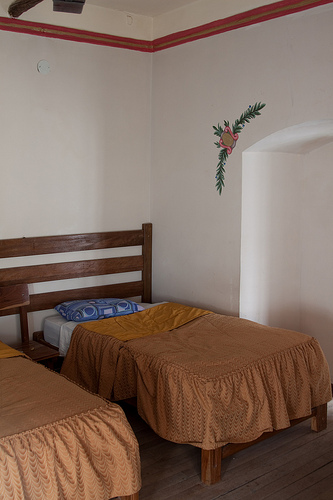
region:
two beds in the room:
[0, 295, 325, 498]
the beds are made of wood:
[1, 224, 330, 498]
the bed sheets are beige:
[1, 303, 327, 498]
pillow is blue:
[58, 292, 141, 322]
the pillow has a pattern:
[59, 289, 137, 322]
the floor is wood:
[132, 393, 332, 495]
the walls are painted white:
[0, 1, 331, 373]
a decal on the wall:
[212, 101, 264, 194]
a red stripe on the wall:
[0, 1, 328, 50]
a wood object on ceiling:
[7, 0, 81, 21]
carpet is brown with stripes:
[244, 455, 287, 493]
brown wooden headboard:
[49, 229, 166, 295]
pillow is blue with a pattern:
[53, 294, 146, 333]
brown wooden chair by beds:
[0, 275, 60, 369]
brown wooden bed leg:
[202, 441, 233, 498]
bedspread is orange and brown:
[158, 348, 236, 417]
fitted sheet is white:
[39, 311, 85, 368]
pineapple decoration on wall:
[200, 79, 263, 194]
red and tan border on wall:
[156, 9, 284, 61]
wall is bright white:
[190, 217, 238, 275]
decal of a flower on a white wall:
[207, 100, 270, 196]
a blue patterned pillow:
[53, 292, 145, 318]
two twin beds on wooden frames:
[0, 221, 332, 499]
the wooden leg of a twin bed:
[200, 449, 221, 485]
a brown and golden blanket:
[58, 301, 324, 449]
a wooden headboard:
[0, 223, 152, 297]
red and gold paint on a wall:
[0, 12, 153, 51]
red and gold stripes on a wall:
[154, 1, 329, 51]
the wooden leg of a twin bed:
[311, 401, 330, 432]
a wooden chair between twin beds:
[0, 283, 57, 367]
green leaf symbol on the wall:
[211, 100, 269, 195]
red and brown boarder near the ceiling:
[0, 0, 332, 53]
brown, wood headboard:
[1, 220, 154, 333]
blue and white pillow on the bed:
[53, 295, 144, 324]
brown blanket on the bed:
[60, 301, 331, 451]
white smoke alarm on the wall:
[35, 57, 53, 76]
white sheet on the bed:
[40, 300, 161, 357]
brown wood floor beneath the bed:
[113, 405, 331, 495]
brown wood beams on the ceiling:
[4, 0, 92, 19]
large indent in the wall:
[236, 115, 331, 381]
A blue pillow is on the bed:
[51, 291, 145, 323]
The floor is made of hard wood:
[110, 415, 328, 491]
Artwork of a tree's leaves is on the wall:
[190, 92, 273, 199]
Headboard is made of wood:
[0, 215, 155, 304]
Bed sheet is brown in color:
[59, 296, 326, 450]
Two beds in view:
[0, 286, 327, 493]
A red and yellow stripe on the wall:
[0, 0, 324, 57]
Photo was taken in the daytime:
[0, 2, 327, 489]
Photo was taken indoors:
[0, 0, 327, 484]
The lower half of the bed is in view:
[2, 353, 156, 498]